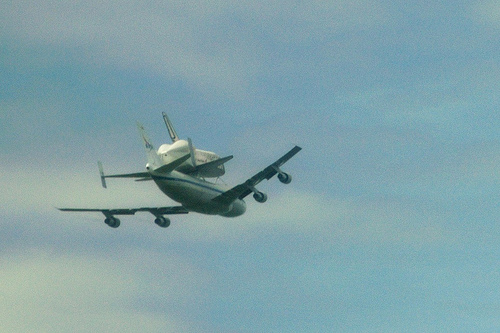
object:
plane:
[57, 110, 302, 228]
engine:
[103, 216, 121, 228]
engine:
[253, 190, 268, 203]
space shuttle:
[55, 111, 301, 229]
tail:
[131, 119, 165, 165]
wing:
[212, 145, 302, 206]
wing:
[54, 205, 188, 229]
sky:
[194, 0, 500, 127]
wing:
[186, 154, 234, 175]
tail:
[159, 109, 180, 142]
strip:
[153, 169, 218, 196]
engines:
[153, 216, 171, 228]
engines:
[277, 172, 292, 185]